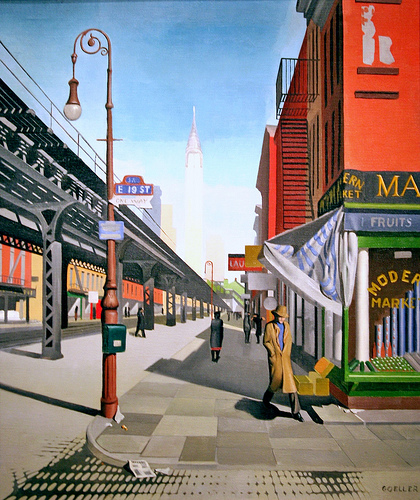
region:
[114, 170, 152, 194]
street sign is blue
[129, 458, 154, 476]
newspaper dropped on street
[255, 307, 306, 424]
man wearing yellow hat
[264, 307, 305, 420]
man wearing yellow coat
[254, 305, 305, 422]
man wearing blue shirt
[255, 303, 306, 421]
man wearing tan pants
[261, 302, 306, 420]
man wearing black shoes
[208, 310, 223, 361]
woman wearing red dress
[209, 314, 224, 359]
woman wearing black coat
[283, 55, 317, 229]
fire escape on red building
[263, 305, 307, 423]
animated man walking down sidewalk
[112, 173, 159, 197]
blue street sign with red metal trim saying 'E 19th ST'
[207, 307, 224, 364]
back of animated woman in knee length black jacket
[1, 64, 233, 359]
animated gray colored ell style train tracks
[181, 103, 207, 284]
Empire State Building in animated scene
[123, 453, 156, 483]
newspaper page blown against sidewalk in animated scene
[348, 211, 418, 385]
window to fruit stand store in animated scene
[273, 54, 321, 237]
fie escape in orange animated building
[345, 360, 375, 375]
zucchini in fruit stands animated store window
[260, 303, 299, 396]
animated matching brown trench coat and hat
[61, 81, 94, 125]
brown light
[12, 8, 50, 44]
white clouds in blue sky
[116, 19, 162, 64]
white clouds in blue sky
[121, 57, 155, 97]
white clouds in blue sky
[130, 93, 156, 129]
white clouds in blue sky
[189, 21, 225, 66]
white clouds in blue sky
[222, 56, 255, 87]
white clouds in blue sky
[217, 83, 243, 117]
white clouds in blue sky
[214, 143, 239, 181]
white clouds in blue sky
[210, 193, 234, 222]
white clouds in blue sky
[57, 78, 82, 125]
The light is off.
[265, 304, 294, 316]
He is wearing a brown hat.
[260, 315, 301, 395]
He is wearing a brown jacket.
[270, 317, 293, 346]
He is wearing a blue shirt.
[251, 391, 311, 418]
He is wearing grey pants.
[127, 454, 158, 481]
The paper is on the ground.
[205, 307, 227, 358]
She is wearing a black jacket.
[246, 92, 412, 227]
The building is red.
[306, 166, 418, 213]
The sign is black.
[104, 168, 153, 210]
The sign is blue.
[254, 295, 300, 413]
brown colored long jacket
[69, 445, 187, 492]
shadow of fence grate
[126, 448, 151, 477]
newspaper on the road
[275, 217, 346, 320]
blue and gray tent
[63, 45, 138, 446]
brown scrolling street light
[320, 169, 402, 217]
black and gold sign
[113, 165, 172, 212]
red and blue street sign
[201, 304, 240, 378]
woman with black jacket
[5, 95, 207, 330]
gray colored bridge for train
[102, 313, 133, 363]
green mail box on pole